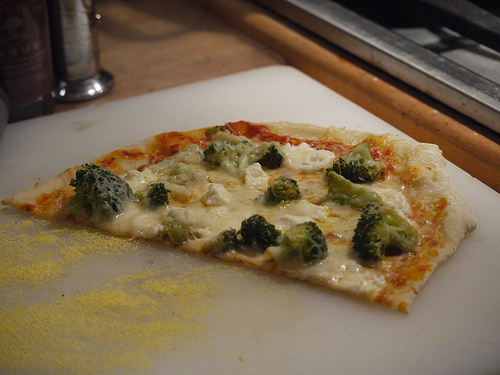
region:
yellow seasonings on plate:
[6, 220, 221, 362]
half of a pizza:
[9, 96, 464, 302]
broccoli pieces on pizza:
[61, 133, 420, 271]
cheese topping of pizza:
[115, 133, 400, 279]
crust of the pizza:
[11, 113, 471, 299]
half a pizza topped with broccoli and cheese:
[26, 102, 496, 308]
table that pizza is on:
[14, 10, 496, 342]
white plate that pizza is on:
[9, 58, 494, 368]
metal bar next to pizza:
[315, 6, 497, 111]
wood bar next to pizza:
[221, 4, 494, 166]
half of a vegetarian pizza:
[8, 9, 498, 349]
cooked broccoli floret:
[70, 159, 130, 219]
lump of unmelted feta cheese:
[199, 180, 229, 212]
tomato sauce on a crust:
[156, 131, 186, 155]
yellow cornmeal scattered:
[22, 222, 156, 329]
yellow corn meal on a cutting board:
[18, 238, 247, 371]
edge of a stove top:
[385, 15, 497, 92]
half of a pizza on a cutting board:
[6, 92, 480, 326]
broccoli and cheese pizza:
[62, 114, 437, 280]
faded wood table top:
[130, 18, 223, 70]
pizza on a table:
[24, 68, 493, 359]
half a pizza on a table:
[42, 34, 494, 339]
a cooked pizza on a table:
[35, 41, 497, 354]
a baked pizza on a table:
[48, 63, 493, 352]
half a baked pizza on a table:
[18, 82, 489, 334]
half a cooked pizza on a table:
[27, 46, 499, 357]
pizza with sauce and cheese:
[80, 50, 496, 357]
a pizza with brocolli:
[41, 41, 467, 374]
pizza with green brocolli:
[50, 54, 496, 372]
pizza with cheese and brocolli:
[23, 44, 497, 367]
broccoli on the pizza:
[67, 162, 123, 224]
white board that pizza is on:
[187, 60, 312, 105]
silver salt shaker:
[42, 0, 114, 105]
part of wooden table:
[180, 19, 297, 56]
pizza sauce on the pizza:
[247, 124, 306, 144]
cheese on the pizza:
[295, 148, 316, 168]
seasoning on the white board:
[15, 268, 183, 339]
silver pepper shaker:
[4, 4, 54, 116]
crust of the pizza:
[420, 150, 452, 192]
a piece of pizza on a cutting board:
[4, 113, 476, 324]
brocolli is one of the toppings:
[63, 153, 125, 220]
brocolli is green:
[68, 166, 143, 223]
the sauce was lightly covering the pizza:
[60, 119, 452, 334]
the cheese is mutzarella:
[289, 143, 329, 175]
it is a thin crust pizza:
[7, 114, 473, 329]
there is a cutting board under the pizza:
[4, 71, 497, 367]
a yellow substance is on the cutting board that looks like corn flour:
[1, 217, 226, 372]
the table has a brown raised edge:
[246, 15, 498, 162]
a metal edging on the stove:
[294, 2, 499, 122]